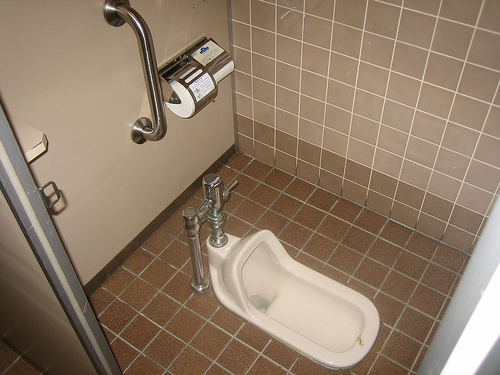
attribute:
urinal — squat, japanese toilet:
[198, 226, 387, 373]